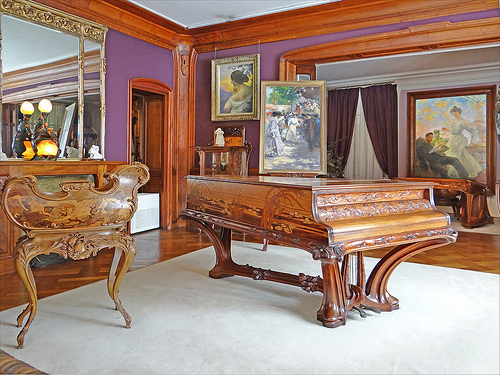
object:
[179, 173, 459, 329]
piano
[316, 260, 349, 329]
leg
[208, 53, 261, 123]
painting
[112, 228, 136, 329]
leg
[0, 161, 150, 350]
furniture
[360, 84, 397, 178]
drape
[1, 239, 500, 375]
rug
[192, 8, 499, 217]
wall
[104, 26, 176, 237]
wall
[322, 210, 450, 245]
cover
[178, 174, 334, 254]
artwork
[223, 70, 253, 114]
woman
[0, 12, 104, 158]
mirror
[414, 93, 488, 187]
painting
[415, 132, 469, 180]
man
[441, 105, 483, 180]
woman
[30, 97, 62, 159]
lamp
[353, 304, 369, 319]
foot pedal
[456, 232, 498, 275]
floor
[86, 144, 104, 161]
statue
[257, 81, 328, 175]
art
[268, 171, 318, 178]
easel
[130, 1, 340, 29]
ceiling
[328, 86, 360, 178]
drape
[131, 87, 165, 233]
doorway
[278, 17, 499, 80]
door frame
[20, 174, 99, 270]
fireplace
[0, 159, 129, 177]
mantle